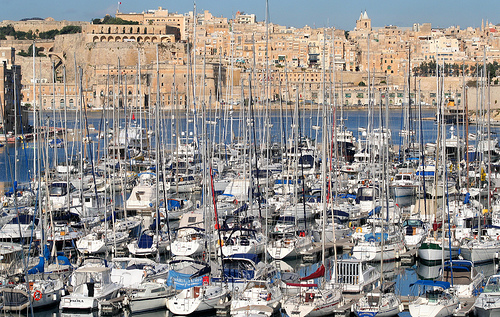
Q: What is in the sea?
A: Ships.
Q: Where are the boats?
A: In the water.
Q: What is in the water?
A: Boats.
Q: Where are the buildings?
A: Across the water.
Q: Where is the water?
A: In front of the city.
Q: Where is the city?
A: On the hill.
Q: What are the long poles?
A: Masts.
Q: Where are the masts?
A: On the board.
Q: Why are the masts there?
A: To hold the sails.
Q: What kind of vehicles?
A: Boats.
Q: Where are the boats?
A: Harbor.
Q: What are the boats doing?
A: Docked.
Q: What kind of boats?
A: Sailboats.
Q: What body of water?
A: Ocean.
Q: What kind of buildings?
A: Tan.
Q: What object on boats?
A: Masts.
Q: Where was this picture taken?
A: At a marina.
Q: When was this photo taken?
A: During the daytime.